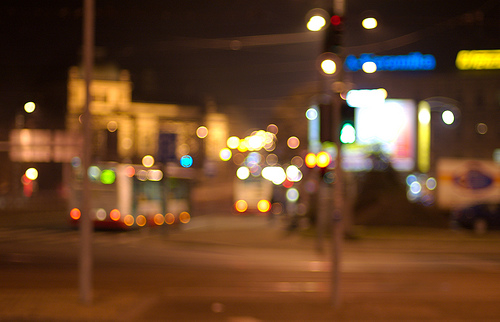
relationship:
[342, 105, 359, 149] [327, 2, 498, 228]
green light on building building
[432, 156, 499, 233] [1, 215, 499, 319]
truck on road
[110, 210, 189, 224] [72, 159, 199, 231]
light on bus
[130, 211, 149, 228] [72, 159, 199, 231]
light on bus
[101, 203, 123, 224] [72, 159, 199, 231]
light on bus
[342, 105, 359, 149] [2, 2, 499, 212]
green light on side of building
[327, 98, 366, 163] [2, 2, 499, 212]
green light on side of building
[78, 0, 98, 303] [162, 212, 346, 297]
pole sticking out of ground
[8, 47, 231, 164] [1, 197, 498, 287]
building along side of road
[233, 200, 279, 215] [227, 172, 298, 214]
lights on vehicle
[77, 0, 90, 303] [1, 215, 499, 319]
pole near road